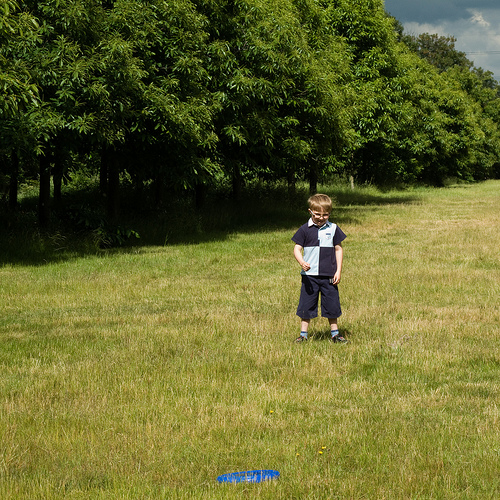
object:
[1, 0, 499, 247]
trees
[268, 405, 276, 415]
yellow weeds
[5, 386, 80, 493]
grass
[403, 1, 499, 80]
sky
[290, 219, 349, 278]
shirt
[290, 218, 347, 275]
checkered shirt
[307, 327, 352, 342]
shadow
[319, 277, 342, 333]
leg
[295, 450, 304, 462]
flower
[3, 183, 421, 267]
shadow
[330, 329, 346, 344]
shoes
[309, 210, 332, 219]
glasses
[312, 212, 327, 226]
face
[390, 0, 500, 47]
blue sky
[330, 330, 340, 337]
socks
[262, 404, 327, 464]
dandelions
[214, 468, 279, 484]
frisbee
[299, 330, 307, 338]
socks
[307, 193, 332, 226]
head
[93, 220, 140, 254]
plant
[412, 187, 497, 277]
grass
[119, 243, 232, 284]
grass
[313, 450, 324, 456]
flower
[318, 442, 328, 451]
flower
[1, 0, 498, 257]
tree row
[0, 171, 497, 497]
field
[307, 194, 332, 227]
boy's head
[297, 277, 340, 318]
shorts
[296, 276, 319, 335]
leg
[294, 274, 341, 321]
black shorts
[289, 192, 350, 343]
boy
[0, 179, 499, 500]
ground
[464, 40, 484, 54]
clouds